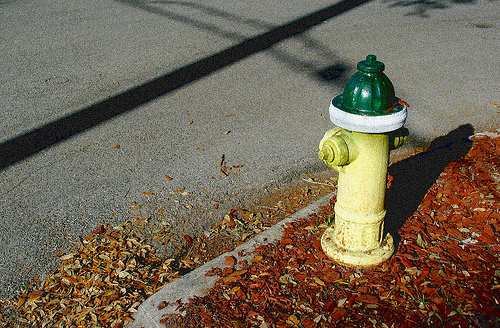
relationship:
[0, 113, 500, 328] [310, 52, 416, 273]
mulch surrounding fire hydrant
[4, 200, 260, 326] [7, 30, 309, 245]
mulch on street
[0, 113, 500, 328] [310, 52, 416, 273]
mulch next to fire hydrant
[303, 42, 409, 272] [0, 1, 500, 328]
fire hydrant next to pavement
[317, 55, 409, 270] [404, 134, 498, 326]
fire hydrant on mulch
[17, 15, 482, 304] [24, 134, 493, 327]
sidewalk covered in leaves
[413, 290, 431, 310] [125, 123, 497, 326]
grass growing on sidewalk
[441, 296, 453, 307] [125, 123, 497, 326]
grass growing on sidewalk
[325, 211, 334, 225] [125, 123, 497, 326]
grass growing on sidewalk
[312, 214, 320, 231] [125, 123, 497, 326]
grass growing on sidewalk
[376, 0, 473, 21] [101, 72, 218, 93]
shadow on pavement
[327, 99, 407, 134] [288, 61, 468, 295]
trim on hydrant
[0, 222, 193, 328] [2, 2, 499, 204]
leaves on pavement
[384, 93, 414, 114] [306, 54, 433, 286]
leaves on top of fire hydrant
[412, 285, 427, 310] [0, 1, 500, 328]
grass beside pavement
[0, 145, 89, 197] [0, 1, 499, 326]
crack on pavement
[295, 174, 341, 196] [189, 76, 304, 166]
small stick laying on road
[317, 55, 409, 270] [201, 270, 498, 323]
fire hydrant covered in dirt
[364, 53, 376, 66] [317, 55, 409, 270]
bolt on top of fire hydrant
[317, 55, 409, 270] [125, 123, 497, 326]
fire hydrant on sidewalk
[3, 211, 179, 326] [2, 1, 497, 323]
leaves on ground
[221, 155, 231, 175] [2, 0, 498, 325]
leaves on road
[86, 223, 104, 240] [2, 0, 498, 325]
leaves on road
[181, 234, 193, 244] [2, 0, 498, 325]
leaves on road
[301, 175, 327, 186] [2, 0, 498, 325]
leaves on road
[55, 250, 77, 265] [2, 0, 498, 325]
leaves on road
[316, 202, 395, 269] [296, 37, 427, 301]
bottom of fire hydrant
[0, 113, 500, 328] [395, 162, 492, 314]
mulch in flower bed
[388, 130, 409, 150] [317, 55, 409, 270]
bolt on fire hydrant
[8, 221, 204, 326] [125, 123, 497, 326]
leaves are along sidewalk